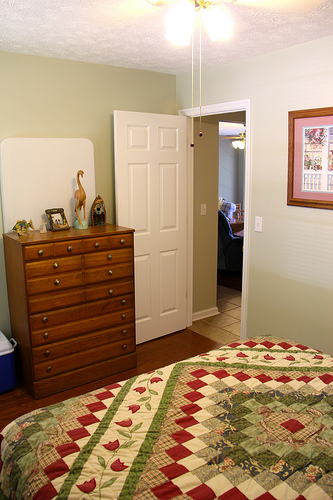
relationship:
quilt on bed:
[9, 337, 332, 500] [2, 337, 332, 499]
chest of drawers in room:
[10, 230, 136, 385] [4, 0, 330, 500]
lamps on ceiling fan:
[169, 11, 190, 46] [135, 3, 282, 43]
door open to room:
[114, 110, 187, 342] [4, 0, 330, 500]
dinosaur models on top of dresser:
[71, 169, 88, 227] [10, 230, 136, 385]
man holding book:
[220, 206, 251, 231] [234, 220, 248, 228]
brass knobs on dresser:
[34, 249, 46, 257] [10, 230, 136, 385]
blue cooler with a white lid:
[2, 351, 13, 387] [2, 334, 12, 350]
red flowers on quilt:
[100, 435, 128, 480] [9, 337, 332, 500]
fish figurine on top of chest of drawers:
[88, 196, 106, 222] [10, 230, 136, 385]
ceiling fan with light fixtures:
[135, 3, 282, 43] [205, 13, 234, 38]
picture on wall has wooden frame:
[293, 112, 331, 204] [286, 111, 333, 121]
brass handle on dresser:
[39, 314, 49, 322] [10, 230, 136, 385]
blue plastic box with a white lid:
[2, 351, 13, 387] [2, 334, 12, 350]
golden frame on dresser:
[6, 241, 37, 394] [10, 230, 136, 385]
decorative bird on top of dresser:
[12, 219, 35, 237] [10, 230, 136, 385]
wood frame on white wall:
[293, 112, 331, 204] [249, 56, 331, 338]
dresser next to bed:
[10, 230, 136, 385] [2, 337, 332, 499]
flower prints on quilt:
[113, 415, 144, 442] [9, 337, 332, 500]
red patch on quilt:
[179, 417, 198, 427] [9, 337, 332, 500]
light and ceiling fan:
[169, 11, 190, 46] [135, 3, 282, 43]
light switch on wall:
[253, 216, 263, 232] [249, 56, 331, 338]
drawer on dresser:
[26, 245, 134, 280] [10, 230, 136, 385]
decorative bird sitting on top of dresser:
[12, 219, 37, 233] [10, 230, 136, 385]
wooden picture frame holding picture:
[285, 110, 295, 206] [293, 112, 331, 204]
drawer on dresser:
[31, 263, 117, 280] [10, 230, 136, 385]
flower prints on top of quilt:
[86, 386, 148, 498] [9, 337, 332, 500]